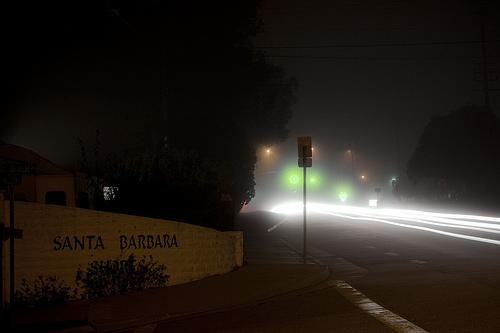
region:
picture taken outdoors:
[75, 47, 360, 325]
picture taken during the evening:
[104, 27, 496, 318]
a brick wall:
[54, 213, 321, 273]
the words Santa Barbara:
[50, 213, 262, 294]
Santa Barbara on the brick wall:
[18, 223, 280, 294]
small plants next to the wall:
[68, 238, 192, 329]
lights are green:
[222, 167, 484, 248]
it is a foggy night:
[245, 67, 423, 319]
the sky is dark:
[291, 24, 475, 181]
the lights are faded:
[248, 93, 422, 287]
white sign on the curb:
[5, 192, 265, 307]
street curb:
[273, 237, 328, 304]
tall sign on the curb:
[280, 113, 330, 294]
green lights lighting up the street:
[275, 164, 342, 205]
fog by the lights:
[266, 136, 353, 239]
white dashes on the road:
[346, 222, 422, 282]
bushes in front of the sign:
[18, 227, 169, 327]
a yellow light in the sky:
[350, 167, 382, 189]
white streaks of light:
[328, 182, 498, 254]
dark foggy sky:
[291, 32, 406, 110]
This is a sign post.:
[290, 130, 328, 266]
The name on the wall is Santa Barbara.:
[48, 228, 198, 256]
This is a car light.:
[278, 195, 495, 240]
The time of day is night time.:
[8, 5, 481, 315]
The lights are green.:
[280, 165, 373, 212]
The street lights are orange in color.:
[263, 130, 378, 184]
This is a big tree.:
[72, 17, 299, 206]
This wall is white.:
[9, 191, 251, 283]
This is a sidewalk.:
[245, 223, 306, 287]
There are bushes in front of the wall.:
[46, 256, 173, 308]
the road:
[317, 185, 414, 325]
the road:
[295, 241, 355, 323]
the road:
[352, 135, 432, 326]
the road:
[369, 170, 412, 329]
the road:
[395, 192, 430, 316]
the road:
[354, 218, 381, 310]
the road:
[353, 200, 395, 323]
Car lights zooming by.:
[322, 173, 497, 260]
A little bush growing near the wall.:
[70, 246, 180, 304]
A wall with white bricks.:
[20, 203, 260, 304]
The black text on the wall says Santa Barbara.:
[47, 228, 183, 253]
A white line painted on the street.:
[321, 276, 432, 331]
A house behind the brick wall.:
[0, 140, 90, 207]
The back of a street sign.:
[285, 112, 326, 268]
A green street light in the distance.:
[282, 155, 302, 190]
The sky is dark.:
[325, 65, 402, 107]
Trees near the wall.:
[105, 38, 281, 218]